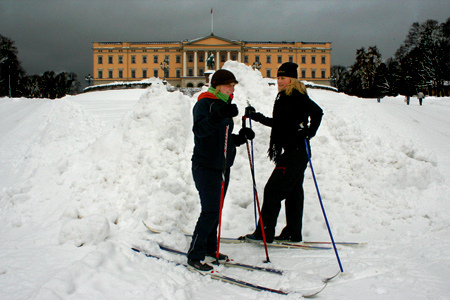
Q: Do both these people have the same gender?
A: Yes, all the people are female.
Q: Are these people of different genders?
A: No, all the people are female.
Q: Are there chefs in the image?
A: No, there are no chefs.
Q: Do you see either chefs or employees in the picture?
A: No, there are no chefs or employees.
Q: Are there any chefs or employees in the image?
A: No, there are no chefs or employees.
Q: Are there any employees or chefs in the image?
A: No, there are no chefs or employees.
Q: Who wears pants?
A: The girl wears pants.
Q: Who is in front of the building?
A: The girl is in front of the building.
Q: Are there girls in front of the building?
A: Yes, there is a girl in front of the building.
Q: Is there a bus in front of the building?
A: No, there is a girl in front of the building.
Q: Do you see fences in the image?
A: No, there are no fences.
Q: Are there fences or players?
A: No, there are no fences or players.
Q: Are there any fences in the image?
A: No, there are no fences.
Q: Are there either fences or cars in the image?
A: No, there are no fences or cars.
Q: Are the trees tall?
A: Yes, the trees are tall.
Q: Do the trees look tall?
A: Yes, the trees are tall.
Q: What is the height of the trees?
A: The trees are tall.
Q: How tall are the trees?
A: The trees are tall.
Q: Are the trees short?
A: No, the trees are tall.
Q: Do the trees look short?
A: No, the trees are tall.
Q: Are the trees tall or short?
A: The trees are tall.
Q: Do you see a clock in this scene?
A: No, there are no clocks.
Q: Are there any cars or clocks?
A: No, there are no clocks or cars.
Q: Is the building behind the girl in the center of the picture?
A: Yes, the building is behind the girl.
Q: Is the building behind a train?
A: No, the building is behind the girl.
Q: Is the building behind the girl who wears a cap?
A: Yes, the building is behind the girl.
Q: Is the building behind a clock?
A: No, the building is behind the girl.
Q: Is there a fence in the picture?
A: No, there are no fences.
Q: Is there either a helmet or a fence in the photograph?
A: No, there are no fences or helmets.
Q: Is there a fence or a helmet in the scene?
A: No, there are no fences or helmets.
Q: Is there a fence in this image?
A: No, there are no fences.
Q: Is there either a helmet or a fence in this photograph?
A: No, there are no fences or helmets.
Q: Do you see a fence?
A: No, there are no fences.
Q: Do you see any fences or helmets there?
A: No, there are no fences or helmets.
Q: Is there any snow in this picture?
A: Yes, there is snow.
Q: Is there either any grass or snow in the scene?
A: Yes, there is snow.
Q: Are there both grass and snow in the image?
A: No, there is snow but no grass.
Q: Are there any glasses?
A: No, there are no glasses.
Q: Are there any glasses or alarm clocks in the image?
A: No, there are no glasses or alarm clocks.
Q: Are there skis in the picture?
A: Yes, there are skis.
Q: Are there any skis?
A: Yes, there are skis.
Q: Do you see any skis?
A: Yes, there are skis.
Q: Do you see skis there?
A: Yes, there are skis.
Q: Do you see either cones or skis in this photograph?
A: Yes, there are skis.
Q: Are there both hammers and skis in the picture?
A: No, there are skis but no hammers.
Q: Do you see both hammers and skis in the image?
A: No, there are skis but no hammers.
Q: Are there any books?
A: No, there are no books.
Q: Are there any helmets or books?
A: No, there are no books or helmets.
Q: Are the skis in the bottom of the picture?
A: Yes, the skis are in the bottom of the image.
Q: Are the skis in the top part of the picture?
A: No, the skis are in the bottom of the image.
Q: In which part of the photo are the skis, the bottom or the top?
A: The skis are in the bottom of the image.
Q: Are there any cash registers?
A: No, there are no cash registers.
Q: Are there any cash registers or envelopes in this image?
A: No, there are no cash registers or envelopes.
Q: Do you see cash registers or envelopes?
A: No, there are no cash registers or envelopes.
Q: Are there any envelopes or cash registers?
A: No, there are no cash registers or envelopes.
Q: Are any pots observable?
A: No, there are no pots.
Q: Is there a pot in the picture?
A: No, there are no pots.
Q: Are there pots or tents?
A: No, there are no pots or tents.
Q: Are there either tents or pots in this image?
A: No, there are no pots or tents.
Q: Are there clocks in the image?
A: No, there are no clocks.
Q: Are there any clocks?
A: No, there are no clocks.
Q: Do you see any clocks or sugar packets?
A: No, there are no clocks or sugar packets.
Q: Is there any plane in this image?
A: No, there are no airplanes.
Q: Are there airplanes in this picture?
A: No, there are no airplanes.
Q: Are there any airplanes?
A: No, there are no airplanes.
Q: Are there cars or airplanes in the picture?
A: No, there are no airplanes or cars.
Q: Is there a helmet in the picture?
A: No, there are no helmets.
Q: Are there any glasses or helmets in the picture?
A: No, there are no helmets or glasses.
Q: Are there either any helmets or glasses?
A: No, there are no helmets or glasses.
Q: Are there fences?
A: No, there are no fences.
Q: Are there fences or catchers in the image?
A: No, there are no fences or catchers.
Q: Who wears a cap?
A: The girl wears a cap.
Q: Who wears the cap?
A: The girl wears a cap.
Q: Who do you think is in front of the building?
A: The girl is in front of the building.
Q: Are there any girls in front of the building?
A: Yes, there is a girl in front of the building.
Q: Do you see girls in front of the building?
A: Yes, there is a girl in front of the building.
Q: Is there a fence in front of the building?
A: No, there is a girl in front of the building.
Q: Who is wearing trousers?
A: The girl is wearing trousers.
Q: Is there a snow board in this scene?
A: No, there are no snowboards.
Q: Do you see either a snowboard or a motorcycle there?
A: No, there are no snowboards or motorcycles.